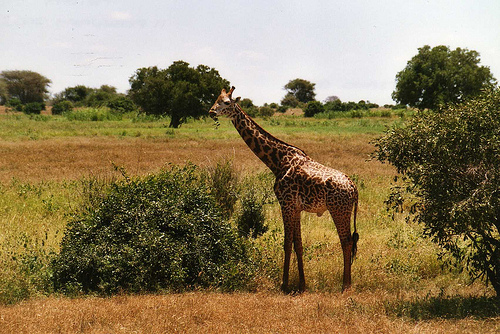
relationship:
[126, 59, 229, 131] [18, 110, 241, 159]
tree on field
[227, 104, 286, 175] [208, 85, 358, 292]
neck on giraffe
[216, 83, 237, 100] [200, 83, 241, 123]
horns on giraffe's head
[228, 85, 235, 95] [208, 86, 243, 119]
horn on giraffe's head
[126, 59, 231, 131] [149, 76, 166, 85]
tree has leaf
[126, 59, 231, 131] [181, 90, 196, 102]
tree has leaf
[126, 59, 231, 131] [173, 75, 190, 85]
tree has leaf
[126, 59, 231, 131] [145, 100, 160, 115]
tree has leaf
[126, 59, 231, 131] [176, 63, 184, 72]
tree has leaf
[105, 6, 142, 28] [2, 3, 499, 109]
cloud in sky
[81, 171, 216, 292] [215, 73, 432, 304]
bush in front of giraffe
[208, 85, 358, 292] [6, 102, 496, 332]
giraffe in a field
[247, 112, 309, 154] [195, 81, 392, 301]
mane of giraffe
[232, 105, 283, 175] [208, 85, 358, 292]
neck of giraffe